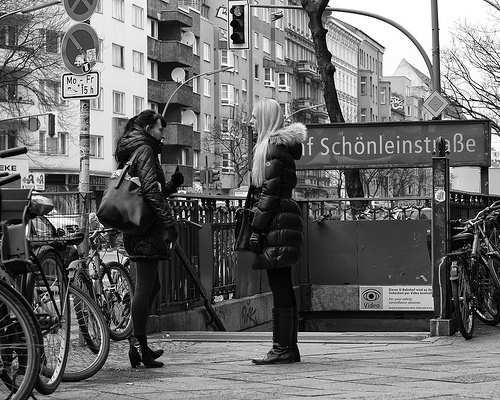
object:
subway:
[130, 169, 451, 341]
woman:
[93, 105, 184, 372]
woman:
[230, 98, 312, 368]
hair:
[249, 96, 283, 187]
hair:
[110, 109, 167, 166]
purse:
[95, 144, 163, 241]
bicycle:
[443, 200, 499, 342]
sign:
[55, 71, 102, 101]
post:
[75, 100, 92, 261]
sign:
[56, 22, 101, 77]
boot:
[249, 304, 297, 367]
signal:
[224, 3, 243, 17]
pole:
[422, 0, 444, 297]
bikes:
[0, 144, 46, 400]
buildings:
[1, 0, 364, 249]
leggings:
[126, 257, 163, 339]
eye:
[359, 287, 383, 304]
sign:
[352, 282, 436, 314]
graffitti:
[236, 298, 260, 326]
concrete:
[154, 285, 302, 337]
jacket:
[248, 121, 309, 272]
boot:
[126, 333, 165, 368]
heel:
[128, 353, 138, 372]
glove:
[168, 164, 184, 188]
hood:
[265, 120, 305, 162]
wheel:
[444, 259, 476, 341]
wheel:
[94, 260, 140, 342]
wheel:
[18, 246, 72, 396]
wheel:
[18, 276, 114, 386]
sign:
[417, 91, 449, 120]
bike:
[61, 223, 138, 356]